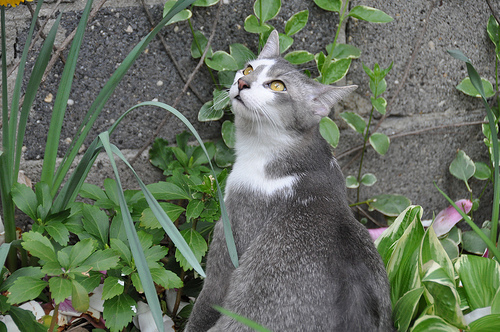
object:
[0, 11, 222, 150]
brick wall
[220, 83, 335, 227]
fur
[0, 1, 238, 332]
grasses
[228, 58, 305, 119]
face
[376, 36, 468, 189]
concrete block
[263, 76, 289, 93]
eye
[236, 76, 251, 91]
nose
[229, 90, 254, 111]
mouth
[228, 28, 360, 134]
head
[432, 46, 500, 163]
leaves wall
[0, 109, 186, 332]
leaves wall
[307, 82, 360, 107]
ear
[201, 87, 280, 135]
whiskers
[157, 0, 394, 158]
ivy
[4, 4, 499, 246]
wall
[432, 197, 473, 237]
bud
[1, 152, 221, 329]
green plants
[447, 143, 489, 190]
leaves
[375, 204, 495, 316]
plant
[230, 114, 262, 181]
white patch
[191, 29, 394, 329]
cat